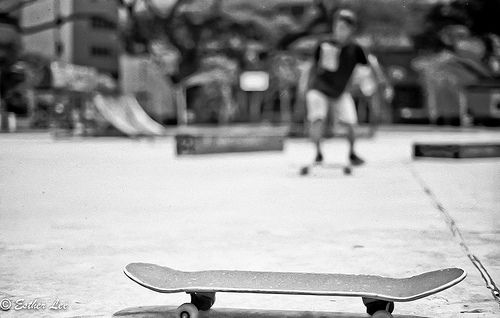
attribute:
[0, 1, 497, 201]
photo — out of focus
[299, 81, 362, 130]
shorts — white 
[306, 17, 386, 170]
man — standing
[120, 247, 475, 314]
skateboard — black 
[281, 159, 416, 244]
sidewalk — gray 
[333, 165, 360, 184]
wheel skateboard — under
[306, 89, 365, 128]
shorts — white 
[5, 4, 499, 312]
photo — taken in the summer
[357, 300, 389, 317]
wheel — white 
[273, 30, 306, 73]
arm — boy's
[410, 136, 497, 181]
ramp — for doing tricks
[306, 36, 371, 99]
shirt — dark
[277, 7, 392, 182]
person — skate boarding, down the street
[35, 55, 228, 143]
ramp — for doing tricks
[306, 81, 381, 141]
shorts — white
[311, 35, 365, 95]
t-shirt — black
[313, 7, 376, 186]
man — on top